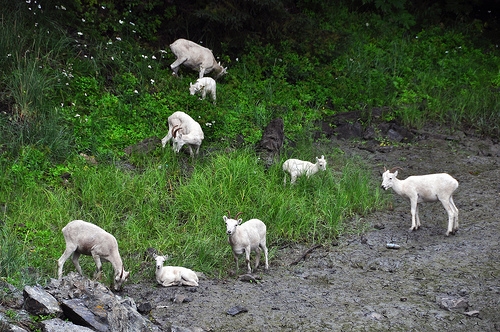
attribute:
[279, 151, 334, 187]
goat — small, white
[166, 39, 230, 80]
goat — white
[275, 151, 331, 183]
goat — medium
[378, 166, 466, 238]
goat — small, white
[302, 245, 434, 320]
dirt — gray, wet-looking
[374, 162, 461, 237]
goat — small, white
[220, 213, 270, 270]
goat —  small , white, baby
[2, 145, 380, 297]
grass — overgrown, healthy, green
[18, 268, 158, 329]
rock pile — small